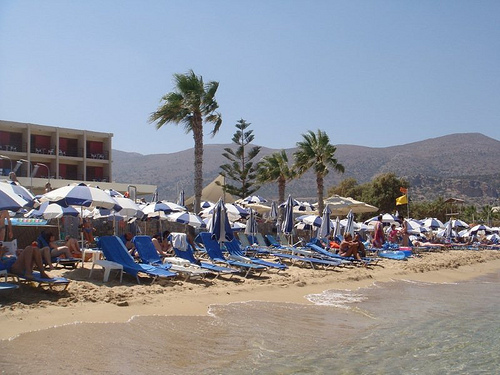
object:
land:
[109, 133, 500, 202]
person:
[408, 234, 444, 248]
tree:
[147, 68, 222, 218]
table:
[89, 260, 124, 283]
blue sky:
[0, 0, 500, 150]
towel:
[170, 236, 233, 272]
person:
[48, 233, 71, 259]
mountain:
[303, 133, 498, 171]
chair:
[222, 232, 270, 259]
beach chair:
[94, 234, 177, 285]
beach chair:
[167, 232, 238, 281]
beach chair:
[199, 232, 266, 278]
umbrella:
[413, 227, 431, 233]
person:
[0, 245, 54, 278]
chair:
[3, 266, 70, 293]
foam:
[1, 278, 499, 375]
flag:
[400, 186, 407, 193]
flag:
[395, 195, 406, 206]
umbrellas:
[92, 196, 144, 219]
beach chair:
[270, 253, 343, 271]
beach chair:
[222, 237, 287, 273]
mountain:
[111, 132, 498, 206]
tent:
[42, 183, 122, 216]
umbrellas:
[91, 188, 136, 221]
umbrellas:
[283, 194, 293, 233]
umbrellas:
[446, 217, 456, 239]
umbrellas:
[166, 211, 207, 229]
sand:
[0, 251, 497, 341]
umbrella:
[138, 200, 187, 215]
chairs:
[264, 234, 296, 257]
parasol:
[31, 182, 124, 214]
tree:
[285, 129, 344, 215]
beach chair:
[131, 235, 208, 283]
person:
[338, 232, 359, 259]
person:
[369, 215, 386, 257]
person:
[389, 224, 399, 244]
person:
[397, 214, 409, 247]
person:
[348, 234, 366, 260]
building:
[0, 118, 159, 257]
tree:
[215, 118, 262, 200]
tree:
[252, 149, 298, 203]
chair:
[36, 230, 83, 269]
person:
[55, 235, 81, 254]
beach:
[2, 227, 499, 371]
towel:
[99, 235, 157, 277]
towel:
[130, 235, 172, 270]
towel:
[168, 232, 188, 252]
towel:
[200, 232, 266, 269]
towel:
[218, 238, 287, 269]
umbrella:
[0, 181, 42, 211]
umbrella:
[7, 194, 79, 220]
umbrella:
[420, 217, 444, 230]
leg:
[11, 246, 33, 275]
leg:
[32, 247, 43, 272]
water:
[3, 267, 498, 373]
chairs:
[335, 234, 384, 257]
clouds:
[0, 0, 500, 155]